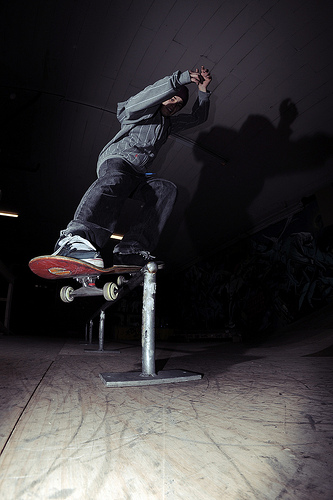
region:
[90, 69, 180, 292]
A man skating under a roof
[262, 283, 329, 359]
A dark photo background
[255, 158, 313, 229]
A dark photo background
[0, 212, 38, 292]
A dark photo background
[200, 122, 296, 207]
A dark photo background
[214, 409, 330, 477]
A rough skating ground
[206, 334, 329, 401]
A rough skating ground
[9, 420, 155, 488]
A rough skating ground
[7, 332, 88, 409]
A rough skating ground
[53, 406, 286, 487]
The ground is made of concrete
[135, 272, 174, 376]
The pole is made of metal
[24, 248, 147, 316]
The skateboard on the pole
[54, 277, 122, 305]
The wheel of the skateboard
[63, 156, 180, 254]
The man has on pants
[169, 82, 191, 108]
The man is wearing a hat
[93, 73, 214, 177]
The man is wearing a sweater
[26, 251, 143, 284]
The bottom of the board is red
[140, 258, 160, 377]
The metal is the color silver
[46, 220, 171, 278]
The shoes of the man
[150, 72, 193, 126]
head of a person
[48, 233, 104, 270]
feet of a person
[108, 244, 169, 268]
feet of a person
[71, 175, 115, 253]
leg of a person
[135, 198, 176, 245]
leg of a person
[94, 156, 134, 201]
thigh of a person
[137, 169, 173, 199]
thigh of a person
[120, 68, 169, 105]
arm of a person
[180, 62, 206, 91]
hand of a person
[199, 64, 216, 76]
fingers of a person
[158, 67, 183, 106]
boy has black hat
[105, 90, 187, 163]
boy has green shirt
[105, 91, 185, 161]
grey stripes on shirt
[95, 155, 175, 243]
boy has black pants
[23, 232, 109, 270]
black and white shoes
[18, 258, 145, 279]
red bottom of board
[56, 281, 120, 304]
white wheels on board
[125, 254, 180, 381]
grey leg on bench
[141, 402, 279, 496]
floor is light brown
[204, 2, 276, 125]
white ceiling above boy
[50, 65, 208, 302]
boy skateboarding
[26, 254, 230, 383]
man is skateboarding across a rail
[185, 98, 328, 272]
the man's large shadow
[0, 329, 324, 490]
scuff marks on the floor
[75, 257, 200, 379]
metal rail for practicing skateboarding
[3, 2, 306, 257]
wooden ceiling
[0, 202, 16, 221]
light on the left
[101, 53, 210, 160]
boy is wearing wearing a grey and white pinstriped jacket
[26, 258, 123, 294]
board underneath is red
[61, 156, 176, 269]
man is wearing black jeans and shoes